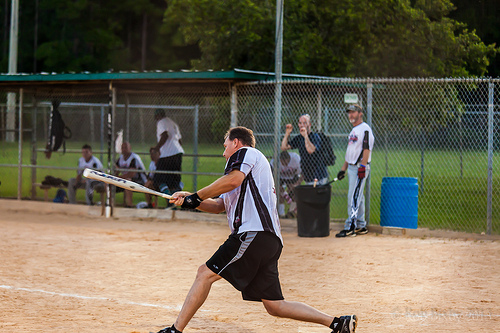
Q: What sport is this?
A: Baseball.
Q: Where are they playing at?
A: Baseball field.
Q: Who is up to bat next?
A: The only other guy on this side of the fence.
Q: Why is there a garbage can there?
A: To put garbage in.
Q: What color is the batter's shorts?
A: Black.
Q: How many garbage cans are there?
A: 2.